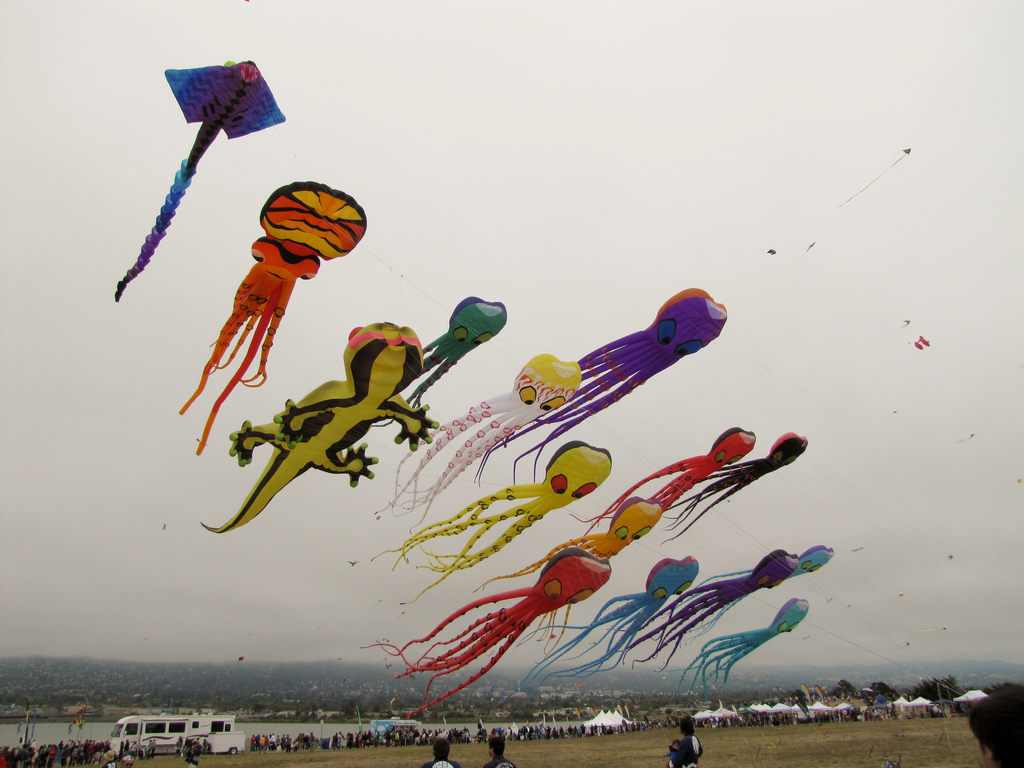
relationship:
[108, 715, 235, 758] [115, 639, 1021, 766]
rv in grass